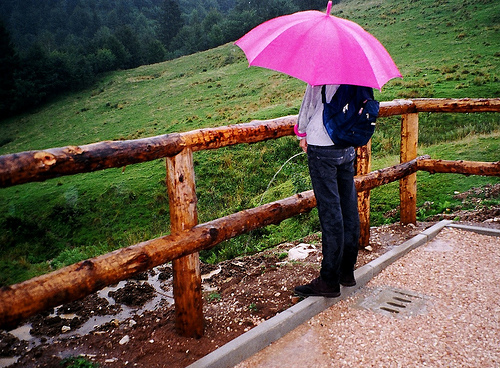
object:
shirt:
[293, 81, 357, 148]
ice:
[84, 312, 127, 336]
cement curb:
[178, 217, 500, 368]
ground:
[416, 238, 495, 276]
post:
[400, 111, 423, 227]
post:
[351, 144, 375, 253]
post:
[160, 134, 207, 337]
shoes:
[334, 268, 358, 287]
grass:
[68, 168, 136, 239]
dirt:
[83, 291, 179, 359]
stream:
[235, 152, 301, 256]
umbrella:
[236, 0, 401, 93]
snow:
[20, 267, 193, 333]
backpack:
[321, 83, 379, 150]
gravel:
[238, 330, 380, 366]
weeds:
[42, 202, 78, 250]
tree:
[2, 2, 99, 120]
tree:
[122, 13, 173, 60]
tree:
[88, 48, 120, 75]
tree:
[197, 8, 232, 50]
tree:
[234, 3, 261, 28]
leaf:
[147, 18, 159, 30]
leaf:
[265, 3, 277, 13]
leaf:
[182, 9, 193, 21]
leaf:
[50, 35, 60, 46]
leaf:
[14, 12, 24, 23]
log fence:
[387, 95, 497, 225]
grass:
[101, 24, 497, 121]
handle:
[293, 122, 308, 139]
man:
[291, 40, 379, 297]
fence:
[0, 96, 500, 340]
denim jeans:
[305, 145, 357, 278]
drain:
[352, 287, 427, 319]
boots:
[294, 273, 342, 297]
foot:
[287, 280, 345, 299]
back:
[323, 84, 385, 153]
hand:
[294, 132, 309, 151]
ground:
[378, 329, 460, 360]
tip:
[294, 135, 306, 141]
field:
[58, 67, 232, 126]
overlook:
[6, 96, 484, 352]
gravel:
[419, 334, 500, 367]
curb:
[193, 222, 496, 367]